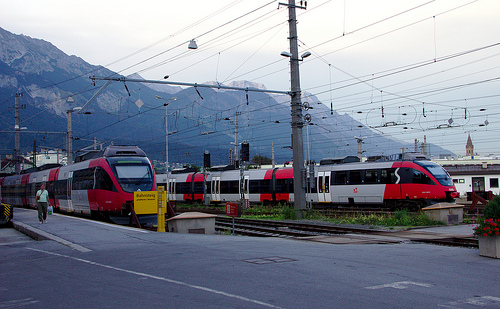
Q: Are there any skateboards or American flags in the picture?
A: No, there are no American flags or skateboards.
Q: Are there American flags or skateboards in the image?
A: No, there are no American flags or skateboards.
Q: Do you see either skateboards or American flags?
A: No, there are no American flags or skateboards.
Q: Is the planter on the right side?
A: Yes, the planter is on the right of the image.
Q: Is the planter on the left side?
A: No, the planter is on the right of the image.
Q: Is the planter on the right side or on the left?
A: The planter is on the right of the image.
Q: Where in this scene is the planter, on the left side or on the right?
A: The planter is on the right of the image.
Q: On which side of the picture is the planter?
A: The planter is on the right of the image.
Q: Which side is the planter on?
A: The planter is on the right of the image.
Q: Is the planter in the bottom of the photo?
A: Yes, the planter is in the bottom of the image.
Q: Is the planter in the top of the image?
A: No, the planter is in the bottom of the image.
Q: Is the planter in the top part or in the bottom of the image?
A: The planter is in the bottom of the image.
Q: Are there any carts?
A: No, there are no carts.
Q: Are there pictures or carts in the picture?
A: No, there are no carts or pictures.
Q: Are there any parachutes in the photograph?
A: No, there are no parachutes.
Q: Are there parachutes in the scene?
A: No, there are no parachutes.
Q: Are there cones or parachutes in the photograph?
A: No, there are no parachutes or cones.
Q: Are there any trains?
A: Yes, there is a train.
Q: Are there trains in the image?
A: Yes, there is a train.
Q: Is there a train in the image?
A: Yes, there is a train.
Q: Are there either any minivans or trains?
A: Yes, there is a train.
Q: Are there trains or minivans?
A: Yes, there is a train.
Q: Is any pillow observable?
A: No, there are no pillows.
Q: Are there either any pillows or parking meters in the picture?
A: No, there are no pillows or parking meters.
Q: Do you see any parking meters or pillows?
A: No, there are no pillows or parking meters.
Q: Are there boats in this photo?
A: No, there are no boats.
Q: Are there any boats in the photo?
A: No, there are no boats.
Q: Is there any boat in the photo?
A: No, there are no boats.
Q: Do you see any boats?
A: No, there are no boats.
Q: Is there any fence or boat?
A: No, there are no boats or fences.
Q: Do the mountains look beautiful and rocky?
A: Yes, the mountains are beautiful and rocky.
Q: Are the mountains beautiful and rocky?
A: Yes, the mountains are beautiful and rocky.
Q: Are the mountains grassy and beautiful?
A: No, the mountains are beautiful but rocky.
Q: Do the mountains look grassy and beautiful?
A: No, the mountains are beautiful but rocky.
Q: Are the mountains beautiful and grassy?
A: No, the mountains are beautiful but rocky.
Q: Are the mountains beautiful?
A: Yes, the mountains are beautiful.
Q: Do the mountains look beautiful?
A: Yes, the mountains are beautiful.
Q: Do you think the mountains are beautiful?
A: Yes, the mountains are beautiful.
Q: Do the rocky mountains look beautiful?
A: Yes, the mountains are beautiful.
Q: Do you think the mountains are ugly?
A: No, the mountains are beautiful.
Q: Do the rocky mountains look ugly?
A: No, the mountains are beautiful.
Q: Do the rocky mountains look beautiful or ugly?
A: The mountains are beautiful.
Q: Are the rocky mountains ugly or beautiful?
A: The mountains are beautiful.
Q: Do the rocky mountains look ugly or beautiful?
A: The mountains are beautiful.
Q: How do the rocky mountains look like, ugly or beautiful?
A: The mountains are beautiful.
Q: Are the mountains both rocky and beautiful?
A: Yes, the mountains are rocky and beautiful.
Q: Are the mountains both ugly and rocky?
A: No, the mountains are rocky but beautiful.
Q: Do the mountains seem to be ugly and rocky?
A: No, the mountains are rocky but beautiful.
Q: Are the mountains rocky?
A: Yes, the mountains are rocky.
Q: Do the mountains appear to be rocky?
A: Yes, the mountains are rocky.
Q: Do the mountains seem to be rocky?
A: Yes, the mountains are rocky.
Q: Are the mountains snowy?
A: No, the mountains are rocky.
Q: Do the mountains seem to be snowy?
A: No, the mountains are rocky.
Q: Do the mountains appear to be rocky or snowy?
A: The mountains are rocky.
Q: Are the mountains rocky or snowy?
A: The mountains are rocky.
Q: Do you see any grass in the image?
A: Yes, there is grass.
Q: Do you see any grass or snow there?
A: Yes, there is grass.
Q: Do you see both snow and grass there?
A: No, there is grass but no snow.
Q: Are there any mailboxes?
A: No, there are no mailboxes.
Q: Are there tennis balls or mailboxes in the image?
A: No, there are no mailboxes or tennis balls.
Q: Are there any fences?
A: No, there are no fences.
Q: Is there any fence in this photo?
A: No, there are no fences.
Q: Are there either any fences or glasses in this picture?
A: No, there are no fences or glasses.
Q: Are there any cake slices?
A: No, there are no cake slices.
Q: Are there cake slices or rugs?
A: No, there are no cake slices or rugs.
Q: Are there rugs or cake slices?
A: No, there are no cake slices or rugs.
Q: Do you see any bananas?
A: Yes, there is a banana.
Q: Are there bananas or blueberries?
A: Yes, there is a banana.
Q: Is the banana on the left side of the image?
A: Yes, the banana is on the left of the image.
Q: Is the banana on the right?
A: No, the banana is on the left of the image.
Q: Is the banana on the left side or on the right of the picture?
A: The banana is on the left of the image.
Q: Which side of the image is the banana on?
A: The banana is on the left of the image.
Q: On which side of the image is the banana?
A: The banana is on the left of the image.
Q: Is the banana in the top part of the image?
A: Yes, the banana is in the top of the image.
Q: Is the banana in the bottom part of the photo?
A: No, the banana is in the top of the image.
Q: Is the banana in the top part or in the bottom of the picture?
A: The banana is in the top of the image.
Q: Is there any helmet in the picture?
A: No, there are no helmets.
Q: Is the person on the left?
A: Yes, the person is on the left of the image.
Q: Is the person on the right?
A: No, the person is on the left of the image.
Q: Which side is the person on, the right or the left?
A: The person is on the left of the image.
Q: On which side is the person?
A: The person is on the left of the image.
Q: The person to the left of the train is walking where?
A: The person is walking on the sidewalk.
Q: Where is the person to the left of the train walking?
A: The person is walking on the sidewalk.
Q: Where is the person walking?
A: The person is walking on the sidewalk.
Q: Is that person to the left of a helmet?
A: No, the person is to the left of the train.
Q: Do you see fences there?
A: No, there are no fences.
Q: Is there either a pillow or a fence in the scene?
A: No, there are no fences or pillows.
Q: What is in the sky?
A: The clouds are in the sky.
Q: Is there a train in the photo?
A: Yes, there is a train.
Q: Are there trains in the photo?
A: Yes, there is a train.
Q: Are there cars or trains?
A: Yes, there is a train.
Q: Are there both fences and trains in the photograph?
A: No, there is a train but no fences.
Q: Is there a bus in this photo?
A: No, there are no buses.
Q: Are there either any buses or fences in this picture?
A: No, there are no buses or fences.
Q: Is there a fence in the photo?
A: No, there are no fences.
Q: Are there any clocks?
A: No, there are no clocks.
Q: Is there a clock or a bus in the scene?
A: No, there are no clocks or buses.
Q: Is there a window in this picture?
A: Yes, there is a window.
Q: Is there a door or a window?
A: Yes, there is a window.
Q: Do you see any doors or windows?
A: Yes, there is a window.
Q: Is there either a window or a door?
A: Yes, there is a window.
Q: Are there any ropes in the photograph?
A: No, there are no ropes.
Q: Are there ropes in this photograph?
A: No, there are no ropes.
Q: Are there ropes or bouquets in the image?
A: No, there are no ropes or bouquets.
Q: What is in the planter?
A: The flowers are in the planter.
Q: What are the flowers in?
A: The flowers are in the planter.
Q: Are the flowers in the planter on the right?
A: Yes, the flowers are in the planter.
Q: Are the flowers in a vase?
A: No, the flowers are in the planter.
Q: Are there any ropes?
A: No, there are no ropes.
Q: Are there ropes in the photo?
A: No, there are no ropes.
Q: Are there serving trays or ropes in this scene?
A: No, there are no ropes or serving trays.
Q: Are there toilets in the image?
A: No, there are no toilets.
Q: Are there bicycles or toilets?
A: No, there are no toilets or bicycles.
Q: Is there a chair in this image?
A: No, there are no chairs.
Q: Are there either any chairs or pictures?
A: No, there are no chairs or pictures.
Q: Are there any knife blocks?
A: No, there are no knife blocks.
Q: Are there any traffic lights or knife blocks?
A: No, there are no knife blocks or traffic lights.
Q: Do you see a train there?
A: Yes, there is a train.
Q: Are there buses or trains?
A: Yes, there is a train.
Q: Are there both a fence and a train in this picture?
A: No, there is a train but no fences.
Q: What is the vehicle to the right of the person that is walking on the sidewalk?
A: The vehicle is a train.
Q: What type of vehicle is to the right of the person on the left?
A: The vehicle is a train.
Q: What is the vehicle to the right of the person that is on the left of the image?
A: The vehicle is a train.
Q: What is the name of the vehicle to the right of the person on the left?
A: The vehicle is a train.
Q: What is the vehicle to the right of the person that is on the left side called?
A: The vehicle is a train.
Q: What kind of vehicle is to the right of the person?
A: The vehicle is a train.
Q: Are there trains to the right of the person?
A: Yes, there is a train to the right of the person.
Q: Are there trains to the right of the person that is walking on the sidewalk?
A: Yes, there is a train to the right of the person.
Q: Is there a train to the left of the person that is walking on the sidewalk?
A: No, the train is to the right of the person.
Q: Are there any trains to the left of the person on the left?
A: No, the train is to the right of the person.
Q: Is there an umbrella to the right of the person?
A: No, there is a train to the right of the person.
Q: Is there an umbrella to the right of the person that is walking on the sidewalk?
A: No, there is a train to the right of the person.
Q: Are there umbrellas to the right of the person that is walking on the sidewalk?
A: No, there is a train to the right of the person.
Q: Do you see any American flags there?
A: No, there are no American flags.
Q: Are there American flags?
A: No, there are no American flags.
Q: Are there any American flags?
A: No, there are no American flags.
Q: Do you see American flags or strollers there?
A: No, there are no American flags or strollers.